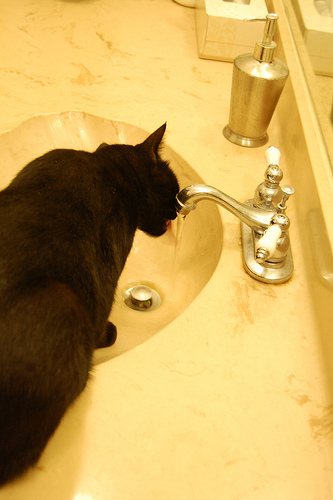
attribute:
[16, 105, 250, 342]
sink — silver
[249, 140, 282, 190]
handle — silver 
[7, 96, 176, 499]
cat — black 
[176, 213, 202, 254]
water — running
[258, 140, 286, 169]
handle — white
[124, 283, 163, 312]
sink stopper — silver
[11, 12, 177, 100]
counter — marble 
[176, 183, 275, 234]
faucet — silver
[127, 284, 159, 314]
sink plug — silver 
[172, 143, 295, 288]
sink hardware — silver 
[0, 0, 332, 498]
countertop — marble 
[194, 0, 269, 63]
box — white 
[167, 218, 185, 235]
tongue — pink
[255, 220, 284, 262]
handle — white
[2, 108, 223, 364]
sink — oval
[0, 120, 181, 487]
cat — black 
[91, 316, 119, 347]
paw — black